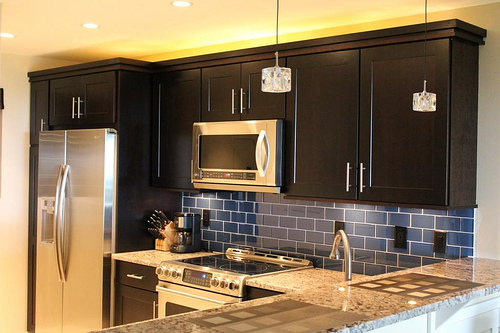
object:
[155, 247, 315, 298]
stove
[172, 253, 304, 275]
flat top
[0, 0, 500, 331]
kitchen room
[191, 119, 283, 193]
microwave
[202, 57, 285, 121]
cabinets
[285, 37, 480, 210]
cabinets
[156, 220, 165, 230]
knives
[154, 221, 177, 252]
block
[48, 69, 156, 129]
cabinets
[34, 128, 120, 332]
fridge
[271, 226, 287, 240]
brick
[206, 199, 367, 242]
wall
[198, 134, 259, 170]
window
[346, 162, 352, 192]
handles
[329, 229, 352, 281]
faucet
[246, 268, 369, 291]
sink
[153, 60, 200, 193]
cupboards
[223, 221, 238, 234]
tile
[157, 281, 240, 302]
silver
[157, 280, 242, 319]
door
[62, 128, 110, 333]
doors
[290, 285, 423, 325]
granite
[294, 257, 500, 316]
top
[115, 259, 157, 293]
drawer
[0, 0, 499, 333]
large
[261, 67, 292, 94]
lights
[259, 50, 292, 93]
down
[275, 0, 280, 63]
cords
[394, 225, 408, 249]
outlets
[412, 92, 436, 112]
cube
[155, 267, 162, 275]
knobs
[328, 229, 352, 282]
metal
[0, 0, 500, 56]
ceiling